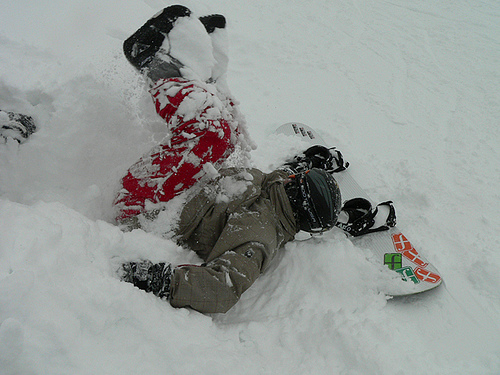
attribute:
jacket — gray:
[166, 178, 286, 312]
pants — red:
[142, 81, 251, 217]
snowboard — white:
[268, 114, 433, 307]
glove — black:
[115, 256, 174, 293]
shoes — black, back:
[125, 11, 225, 55]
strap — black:
[314, 147, 391, 254]